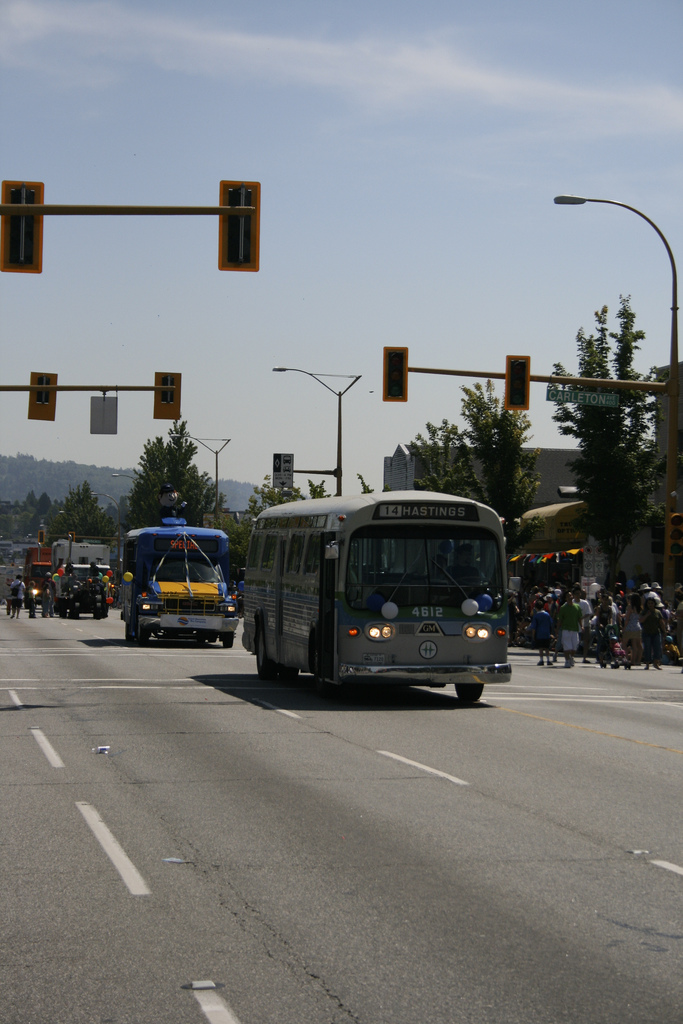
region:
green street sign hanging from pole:
[544, 374, 623, 416]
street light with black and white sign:
[269, 363, 355, 497]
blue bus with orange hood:
[121, 518, 241, 658]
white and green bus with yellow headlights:
[240, 491, 511, 701]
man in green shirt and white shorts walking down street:
[555, 588, 589, 666]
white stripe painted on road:
[72, 794, 157, 906]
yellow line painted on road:
[485, 696, 680, 763]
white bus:
[232, 479, 540, 703]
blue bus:
[107, 516, 222, 646]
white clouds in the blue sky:
[210, 11, 272, 79]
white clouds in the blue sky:
[353, 104, 427, 162]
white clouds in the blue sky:
[193, 282, 239, 315]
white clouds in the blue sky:
[419, 260, 467, 320]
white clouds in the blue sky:
[419, 110, 495, 168]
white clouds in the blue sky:
[23, 22, 112, 94]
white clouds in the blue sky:
[456, 18, 555, 121]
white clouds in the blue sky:
[146, 69, 190, 106]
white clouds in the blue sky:
[101, 272, 159, 314]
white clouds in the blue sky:
[191, 292, 247, 350]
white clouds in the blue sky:
[310, 286, 350, 326]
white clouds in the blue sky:
[355, 262, 429, 322]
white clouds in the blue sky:
[460, 122, 526, 170]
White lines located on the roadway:
[17, 716, 259, 1022]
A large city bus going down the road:
[226, 483, 523, 725]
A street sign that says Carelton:
[535, 349, 633, 424]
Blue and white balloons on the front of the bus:
[337, 581, 526, 681]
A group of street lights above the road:
[16, 337, 554, 424]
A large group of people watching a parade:
[516, 577, 671, 672]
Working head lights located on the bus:
[340, 589, 510, 651]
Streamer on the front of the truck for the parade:
[137, 520, 233, 598]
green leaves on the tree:
[616, 486, 637, 492]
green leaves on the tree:
[461, 417, 493, 465]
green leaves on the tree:
[481, 394, 507, 433]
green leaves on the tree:
[133, 468, 198, 536]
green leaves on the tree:
[149, 424, 175, 456]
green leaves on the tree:
[52, 498, 78, 511]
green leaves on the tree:
[188, 485, 210, 517]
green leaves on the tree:
[136, 424, 180, 468]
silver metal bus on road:
[240, 481, 523, 719]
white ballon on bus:
[375, 593, 401, 625]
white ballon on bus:
[460, 593, 477, 628]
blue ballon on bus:
[469, 588, 497, 613]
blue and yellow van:
[115, 510, 252, 652]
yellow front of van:
[154, 571, 220, 600]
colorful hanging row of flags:
[506, 536, 583, 576]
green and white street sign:
[540, 383, 626, 408]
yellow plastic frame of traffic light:
[498, 349, 537, 411]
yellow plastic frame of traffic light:
[374, 337, 416, 414]